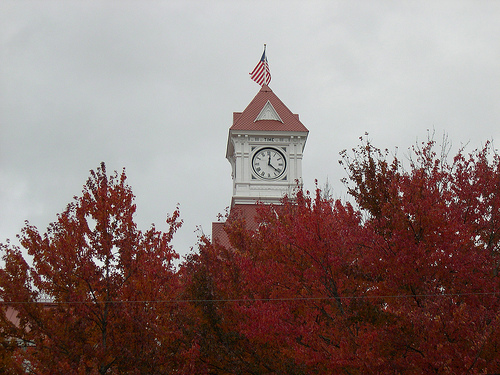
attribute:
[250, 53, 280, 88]
flag — american, red, white, blue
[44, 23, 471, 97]
sky — grey, hazy, cloudy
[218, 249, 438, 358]
tree — colorful, leafy, tall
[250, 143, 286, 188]
clock — white, round, 12:20, black, 12:25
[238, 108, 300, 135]
roof — brown, red, pointy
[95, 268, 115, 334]
branch — colorful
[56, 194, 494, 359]
trees — red, pretty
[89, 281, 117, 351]
branches — dark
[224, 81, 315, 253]
tower — white, tall, red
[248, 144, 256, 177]
border — black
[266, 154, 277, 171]
hands — black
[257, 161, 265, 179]
numbers — roman, black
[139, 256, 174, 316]
leaves — red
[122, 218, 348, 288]
season — autumn